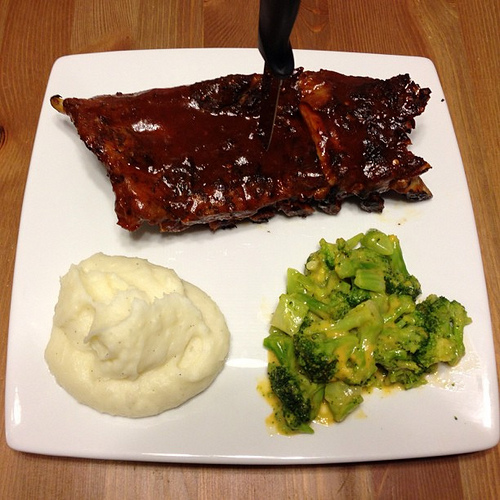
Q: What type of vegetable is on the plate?
A: Broccoli.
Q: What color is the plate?
A: White.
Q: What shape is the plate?
A: White.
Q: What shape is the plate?
A: Rectangular.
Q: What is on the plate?
A: Food.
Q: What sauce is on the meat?
A: BBQ.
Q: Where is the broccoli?
A: Right.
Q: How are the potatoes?
A: Mashed.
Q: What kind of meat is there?
A: Ribs.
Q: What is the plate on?
A: Table.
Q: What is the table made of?
A: Wood.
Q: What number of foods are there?
A: 3.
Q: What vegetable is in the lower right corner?
A: Broccoli.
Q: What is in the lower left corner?
A: Mashed potatoes.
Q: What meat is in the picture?
A: Ribs.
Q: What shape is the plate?
A: Square.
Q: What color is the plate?
A: White.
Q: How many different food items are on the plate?
A: Three.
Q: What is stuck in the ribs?
A: A knife.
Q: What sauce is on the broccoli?
A: Cheese.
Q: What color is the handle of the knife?
A: Black.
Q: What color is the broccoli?
A: Green.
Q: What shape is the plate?
A: Square.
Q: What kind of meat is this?
A: Ribs.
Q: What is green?
A: Broccoli.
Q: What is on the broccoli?
A: Cheese.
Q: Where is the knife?
A: Sticking out of the ribs.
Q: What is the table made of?
A: Wood.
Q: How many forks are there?
A: None.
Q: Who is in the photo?
A: Nobody.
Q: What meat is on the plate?
A: Ribs.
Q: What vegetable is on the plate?
A: Broccoli.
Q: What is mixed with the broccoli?
A: Cheese.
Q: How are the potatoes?
A: Mashed.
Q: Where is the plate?
A: On the table.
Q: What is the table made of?
A: Wood.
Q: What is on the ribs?
A: Sauce.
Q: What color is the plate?
A: White.